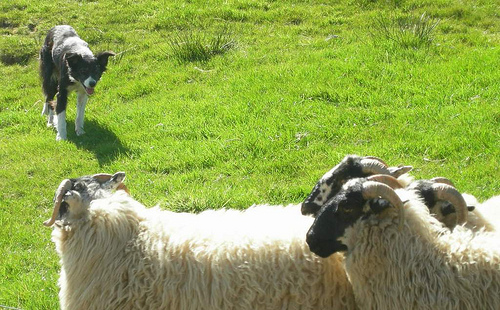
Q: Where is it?
A: This is at the field.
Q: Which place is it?
A: It is a field.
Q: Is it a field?
A: Yes, it is a field.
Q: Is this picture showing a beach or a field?
A: It is showing a field.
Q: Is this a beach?
A: No, it is a field.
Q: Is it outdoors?
A: Yes, it is outdoors.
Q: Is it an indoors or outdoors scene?
A: It is outdoors.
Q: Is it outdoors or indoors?
A: It is outdoors.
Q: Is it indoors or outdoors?
A: It is outdoors.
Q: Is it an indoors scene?
A: No, it is outdoors.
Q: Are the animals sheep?
A: No, there are both sheep and dogs.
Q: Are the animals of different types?
A: Yes, they are sheep and dogs.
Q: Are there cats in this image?
A: No, there are no cats.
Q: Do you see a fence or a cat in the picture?
A: No, there are no cats or fences.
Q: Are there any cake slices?
A: No, there are no cake slices.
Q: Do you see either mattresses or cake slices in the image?
A: No, there are no cake slices or mattresses.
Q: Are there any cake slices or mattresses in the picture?
A: No, there are no cake slices or mattresses.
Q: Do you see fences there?
A: No, there are no fences.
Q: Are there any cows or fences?
A: No, there are no fences or cows.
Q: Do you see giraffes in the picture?
A: No, there are no giraffes.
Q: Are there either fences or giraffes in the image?
A: No, there are no giraffes or fences.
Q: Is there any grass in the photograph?
A: Yes, there is grass.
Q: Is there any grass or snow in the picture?
A: Yes, there is grass.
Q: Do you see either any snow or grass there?
A: Yes, there is grass.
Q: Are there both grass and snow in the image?
A: No, there is grass but no snow.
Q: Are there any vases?
A: No, there are no vases.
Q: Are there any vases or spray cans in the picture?
A: No, there are no vases or spray cans.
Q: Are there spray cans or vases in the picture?
A: No, there are no vases or spray cans.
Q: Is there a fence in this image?
A: No, there are no fences.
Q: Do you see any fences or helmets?
A: No, there are no fences or helmets.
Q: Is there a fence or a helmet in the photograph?
A: No, there are no fences or helmets.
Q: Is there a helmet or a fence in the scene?
A: No, there are no fences or helmets.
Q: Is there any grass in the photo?
A: Yes, there is grass.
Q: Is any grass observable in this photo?
A: Yes, there is grass.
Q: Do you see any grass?
A: Yes, there is grass.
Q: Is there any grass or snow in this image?
A: Yes, there is grass.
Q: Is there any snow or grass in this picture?
A: Yes, there is grass.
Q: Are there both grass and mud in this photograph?
A: No, there is grass but no mud.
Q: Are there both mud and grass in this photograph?
A: No, there is grass but no mud.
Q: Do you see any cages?
A: No, there are no cages.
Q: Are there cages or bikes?
A: No, there are no cages or bikes.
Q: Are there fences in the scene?
A: No, there are no fences.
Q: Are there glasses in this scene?
A: No, there are no glasses.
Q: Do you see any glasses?
A: No, there are no glasses.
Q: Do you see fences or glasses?
A: No, there are no glasses or fences.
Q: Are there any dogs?
A: Yes, there is a dog.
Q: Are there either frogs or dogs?
A: Yes, there is a dog.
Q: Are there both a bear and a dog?
A: No, there is a dog but no bears.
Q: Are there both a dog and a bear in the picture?
A: No, there is a dog but no bears.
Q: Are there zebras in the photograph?
A: No, there are no zebras.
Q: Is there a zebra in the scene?
A: No, there are no zebras.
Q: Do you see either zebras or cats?
A: No, there are no zebras or cats.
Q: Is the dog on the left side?
A: Yes, the dog is on the left of the image.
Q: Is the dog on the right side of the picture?
A: No, the dog is on the left of the image.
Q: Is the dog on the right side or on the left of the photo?
A: The dog is on the left of the image.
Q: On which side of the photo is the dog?
A: The dog is on the left of the image.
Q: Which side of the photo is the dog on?
A: The dog is on the left of the image.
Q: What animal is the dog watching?
A: The dog is watching the sheep.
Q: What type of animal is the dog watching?
A: The dog is watching the sheep.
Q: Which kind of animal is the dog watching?
A: The dog is watching the sheep.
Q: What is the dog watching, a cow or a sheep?
A: The dog is watching a sheep.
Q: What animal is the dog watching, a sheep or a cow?
A: The dog is watching a sheep.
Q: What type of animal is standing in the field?
A: The animal is a dog.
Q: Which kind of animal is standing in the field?
A: The animal is a dog.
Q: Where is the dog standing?
A: The dog is standing in the field.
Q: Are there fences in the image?
A: No, there are no fences.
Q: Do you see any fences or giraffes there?
A: No, there are no fences or giraffes.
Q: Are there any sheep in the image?
A: Yes, there is a sheep.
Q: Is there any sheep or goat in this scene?
A: Yes, there is a sheep.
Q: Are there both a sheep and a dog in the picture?
A: Yes, there are both a sheep and a dog.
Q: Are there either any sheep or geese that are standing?
A: Yes, the sheep is standing.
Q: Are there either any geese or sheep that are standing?
A: Yes, the sheep is standing.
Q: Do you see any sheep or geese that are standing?
A: Yes, the sheep is standing.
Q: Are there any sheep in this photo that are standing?
A: Yes, there is a sheep that is standing.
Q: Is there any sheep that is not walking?
A: Yes, there is a sheep that is standing.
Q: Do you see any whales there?
A: No, there are no whales.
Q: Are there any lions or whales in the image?
A: No, there are no whales or lions.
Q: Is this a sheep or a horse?
A: This is a sheep.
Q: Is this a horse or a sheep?
A: This is a sheep.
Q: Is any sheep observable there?
A: Yes, there is a sheep.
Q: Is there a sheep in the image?
A: Yes, there is a sheep.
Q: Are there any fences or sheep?
A: Yes, there is a sheep.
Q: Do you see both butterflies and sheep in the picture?
A: No, there is a sheep but no butterflies.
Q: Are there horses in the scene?
A: No, there are no horses.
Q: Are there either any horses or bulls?
A: No, there are no horses or bulls.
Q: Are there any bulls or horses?
A: No, there are no horses or bulls.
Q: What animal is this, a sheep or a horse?
A: This is a sheep.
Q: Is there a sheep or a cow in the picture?
A: Yes, there is a sheep.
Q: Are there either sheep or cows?
A: Yes, there is a sheep.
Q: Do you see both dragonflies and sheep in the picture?
A: No, there is a sheep but no dragonflies.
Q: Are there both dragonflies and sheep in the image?
A: No, there is a sheep but no dragonflies.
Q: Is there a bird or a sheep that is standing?
A: Yes, the sheep is standing.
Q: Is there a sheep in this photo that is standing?
A: Yes, there is a sheep that is standing.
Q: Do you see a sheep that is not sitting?
A: Yes, there is a sheep that is standing .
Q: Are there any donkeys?
A: No, there are no donkeys.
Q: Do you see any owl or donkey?
A: No, there are no donkeys or owls.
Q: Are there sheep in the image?
A: Yes, there is a sheep.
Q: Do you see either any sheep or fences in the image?
A: Yes, there is a sheep.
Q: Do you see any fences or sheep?
A: Yes, there is a sheep.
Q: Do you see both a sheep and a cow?
A: No, there is a sheep but no cows.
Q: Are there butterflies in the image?
A: No, there are no butterflies.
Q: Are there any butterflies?
A: No, there are no butterflies.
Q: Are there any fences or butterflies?
A: No, there are no butterflies or fences.